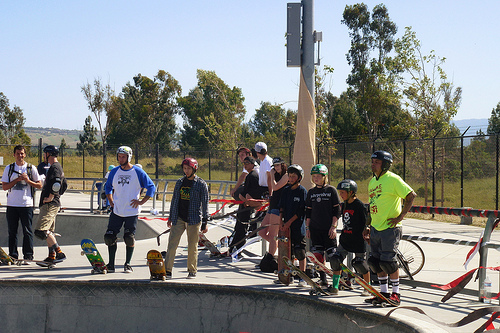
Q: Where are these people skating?
A: Skatepark.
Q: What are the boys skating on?
A: Skateboards.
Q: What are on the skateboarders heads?
A: Helmets.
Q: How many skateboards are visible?
A: Eight.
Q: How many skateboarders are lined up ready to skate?
A: Seven.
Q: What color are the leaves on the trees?
A: Green.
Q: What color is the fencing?
A: Black.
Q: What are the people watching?
A: Skaters.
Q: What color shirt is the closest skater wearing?
A: Yellow.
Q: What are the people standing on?
A: Skateboards.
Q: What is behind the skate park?
A: Trees.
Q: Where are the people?
A: At a skatepark.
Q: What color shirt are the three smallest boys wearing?
A: Black.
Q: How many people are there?
A: 11.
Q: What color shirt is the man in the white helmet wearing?
A: Blue and white.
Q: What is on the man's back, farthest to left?
A: Backpack.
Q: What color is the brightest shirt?
A: Yellow.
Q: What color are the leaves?
A: Green.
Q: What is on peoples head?
A: Helmets.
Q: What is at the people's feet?
A: Skateboards.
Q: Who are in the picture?
A: Skateboarders.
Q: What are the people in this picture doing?
A: Skateboarding.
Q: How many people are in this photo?
A: Twelve.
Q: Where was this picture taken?
A: A skate park.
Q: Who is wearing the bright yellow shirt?
A: The man on the right.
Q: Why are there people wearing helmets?
A: Safety.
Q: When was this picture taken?
A: During the day.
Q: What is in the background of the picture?
A: Trees.